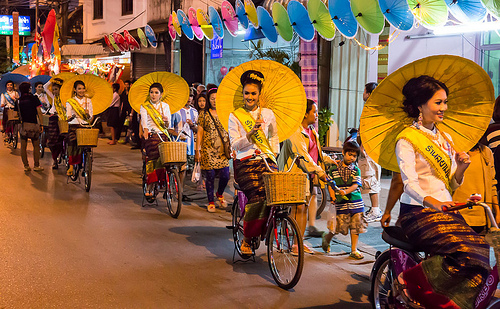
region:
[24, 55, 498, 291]
A large group of asian women riding bikes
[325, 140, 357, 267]
A little boy in a green shirt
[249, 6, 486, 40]
Blue and green umbrellas hanging down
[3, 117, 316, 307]
A group of bicycles with baskets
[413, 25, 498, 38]
a fluorescent light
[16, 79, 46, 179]
a man in a black shirt walking with a bag on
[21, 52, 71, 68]
decorative lights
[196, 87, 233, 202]
woman in a cheetah print dress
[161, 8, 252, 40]
a group of blue, yellow, and pink umbrellas hanging down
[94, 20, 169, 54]
a group of red, green, and blue unbrellas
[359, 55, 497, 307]
girl on bike in front of line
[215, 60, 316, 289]
second girl in line on bike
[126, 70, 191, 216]
third girl in line on bike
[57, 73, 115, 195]
fourth girl in line on bike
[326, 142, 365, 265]
little boy with blue and green striped shirt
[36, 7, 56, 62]
large red umbrella hanging sideways in background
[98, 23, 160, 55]
line of six small umbrellas, red, green, red, red, green, blue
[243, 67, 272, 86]
flowers of hair of second girl in line on bike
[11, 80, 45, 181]
person in black shirt facing away from camera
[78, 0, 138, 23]
windows on white building in background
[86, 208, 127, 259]
edge of a road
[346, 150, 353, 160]
face of a boy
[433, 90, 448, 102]
face of a woman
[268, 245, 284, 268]
wheel of a bike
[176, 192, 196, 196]
front of a bike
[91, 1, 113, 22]
part of a building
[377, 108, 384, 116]
part of an umbrella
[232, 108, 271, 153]
the sash is yellow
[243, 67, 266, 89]
flowers in the hair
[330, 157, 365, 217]
child shirt is striped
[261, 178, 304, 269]
the basket is tan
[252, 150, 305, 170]
the handles are silver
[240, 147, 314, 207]
the handles above basket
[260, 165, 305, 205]
the basket is woven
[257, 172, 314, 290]
basket is above wheel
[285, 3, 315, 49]
the umbrella is blue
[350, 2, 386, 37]
the umbrella is green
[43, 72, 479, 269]
a group of women riding bikes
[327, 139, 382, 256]
young boy in a green shirt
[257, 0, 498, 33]
a line of blue and green umbrellas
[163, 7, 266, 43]
a line of pink, yellow, and blue umbrellas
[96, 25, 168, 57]
a line of red, green, and blue umbrellas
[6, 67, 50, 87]
a pair of blue umbrellas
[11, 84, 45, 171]
a man with a bag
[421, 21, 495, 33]
a fluorescent light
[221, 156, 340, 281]
a bike with a wicker basket on the front